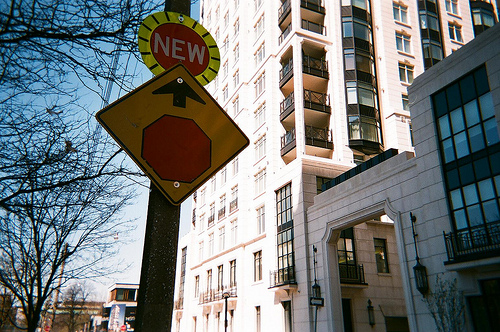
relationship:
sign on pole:
[131, 10, 229, 82] [131, 173, 187, 329]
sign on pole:
[137, 10, 222, 86] [135, 1, 196, 329]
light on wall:
[408, 255, 440, 302] [165, 62, 388, 296]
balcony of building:
[273, 18, 340, 59] [196, 0, 471, 330]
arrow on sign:
[150, 76, 207, 108] [96, 60, 253, 202]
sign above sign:
[137, 10, 222, 86] [96, 60, 253, 202]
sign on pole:
[96, 60, 253, 202] [143, 194, 176, 330]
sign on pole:
[137, 10, 222, 86] [143, 194, 176, 330]